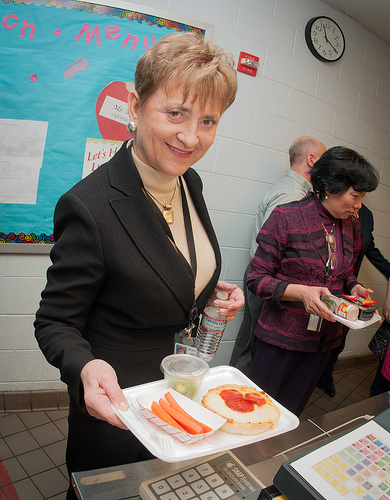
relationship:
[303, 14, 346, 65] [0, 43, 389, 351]
clock on wall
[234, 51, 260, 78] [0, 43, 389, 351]
fire alarm on a wall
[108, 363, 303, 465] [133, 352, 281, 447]
lunch tray with food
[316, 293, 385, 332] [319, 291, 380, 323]
lunch tray with food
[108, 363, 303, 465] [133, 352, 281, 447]
lunch tray with carrots and pizza br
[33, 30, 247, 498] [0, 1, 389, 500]
lady in a cafeteria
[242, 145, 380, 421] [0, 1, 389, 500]
lady in a cafeteria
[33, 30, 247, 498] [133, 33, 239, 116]
lady has short hair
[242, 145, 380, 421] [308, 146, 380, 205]
lady has short hair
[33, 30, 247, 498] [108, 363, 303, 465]
lady carrying a cafeteria tray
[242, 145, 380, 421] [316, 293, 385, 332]
lady carrying a cafeteria tray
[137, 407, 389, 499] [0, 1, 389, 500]
cash register in a cafeteria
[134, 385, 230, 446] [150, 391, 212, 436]
paper boat contains carrot sticks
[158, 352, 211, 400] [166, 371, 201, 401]
cup full of kiwi slices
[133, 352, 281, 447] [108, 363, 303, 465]
food to eat on top of tray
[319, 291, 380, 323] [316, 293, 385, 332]
food to eat on top of tray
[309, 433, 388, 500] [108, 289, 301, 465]
buttons for ringing up sales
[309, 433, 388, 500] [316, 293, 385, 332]
buttons for ringing up sales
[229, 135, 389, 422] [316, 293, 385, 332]
more people waiting in line to p their food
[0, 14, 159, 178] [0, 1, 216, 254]
words on bulletin board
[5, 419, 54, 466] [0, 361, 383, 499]
part of tiled floor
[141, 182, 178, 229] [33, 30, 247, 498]
necklace worn by lady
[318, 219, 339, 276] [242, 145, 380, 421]
necklace worn by lady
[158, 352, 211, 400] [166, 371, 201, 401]
container contains food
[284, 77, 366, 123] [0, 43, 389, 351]
portion of wall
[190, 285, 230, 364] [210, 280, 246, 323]
bottle in hand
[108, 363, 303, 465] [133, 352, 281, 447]
tray contains food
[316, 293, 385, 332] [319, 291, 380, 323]
tray contains food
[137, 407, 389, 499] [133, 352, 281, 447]
register for ringing up food to eat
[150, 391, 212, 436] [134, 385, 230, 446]
carrot sticks are in a paper basket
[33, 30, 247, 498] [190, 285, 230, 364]
woman holding water bottle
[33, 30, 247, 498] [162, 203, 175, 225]
woman wearing a gold pendant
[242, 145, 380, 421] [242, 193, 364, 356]
woman wearing a purple and black jac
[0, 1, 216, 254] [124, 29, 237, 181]
board behind woman's head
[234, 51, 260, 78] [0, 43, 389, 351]
alarm on a tile wall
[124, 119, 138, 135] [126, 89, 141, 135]
earring on a woman's ear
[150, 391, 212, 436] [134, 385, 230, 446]
carrots in a container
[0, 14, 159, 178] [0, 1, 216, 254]
words are on a bulletin board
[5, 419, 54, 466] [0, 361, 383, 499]
part of tile floor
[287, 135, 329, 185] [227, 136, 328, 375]
head and ear of man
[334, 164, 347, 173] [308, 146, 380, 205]
portion of black hair